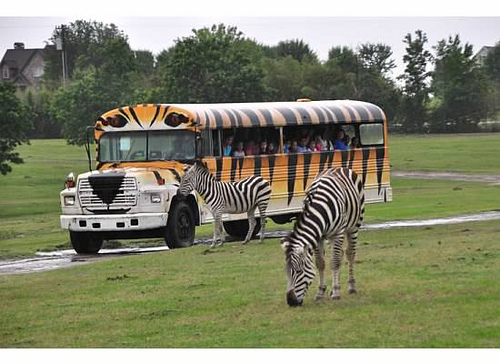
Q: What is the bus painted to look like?
A: A tiger.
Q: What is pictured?
A: A bus and two zebras.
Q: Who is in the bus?
A: Lots of people.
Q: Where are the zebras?
A: In a field.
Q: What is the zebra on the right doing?
A: Eating grass.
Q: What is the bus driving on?
A: A road going through the field.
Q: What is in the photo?
A: Zebras.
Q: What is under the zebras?
A: Grass.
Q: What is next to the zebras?
A: A bus.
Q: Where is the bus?
A: Next to zebras.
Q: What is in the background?
A: Trees.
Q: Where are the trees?
A: In the distance.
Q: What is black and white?
A: The zebras.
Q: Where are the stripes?
A: On the zebras.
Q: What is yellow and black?
A: The bus.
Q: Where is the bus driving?
A: On path.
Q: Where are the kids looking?
A: Out window.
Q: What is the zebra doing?
A: Eating grass.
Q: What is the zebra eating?
A: Grass.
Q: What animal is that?
A: Zebra.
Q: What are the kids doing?
A: Looking out the window.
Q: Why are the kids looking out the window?
A: To look at zebras.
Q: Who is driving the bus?
A: The bus driver.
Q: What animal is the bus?
A: Tiger.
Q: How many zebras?
A: 2.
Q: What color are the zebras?
A: Black n white.